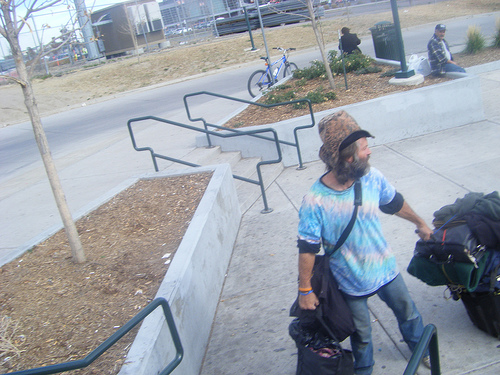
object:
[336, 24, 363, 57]
person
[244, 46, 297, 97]
bike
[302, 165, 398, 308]
teeshirt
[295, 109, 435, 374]
man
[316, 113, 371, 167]
hat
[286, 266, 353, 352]
bag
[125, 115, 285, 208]
railings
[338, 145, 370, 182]
beard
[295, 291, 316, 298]
bracelet